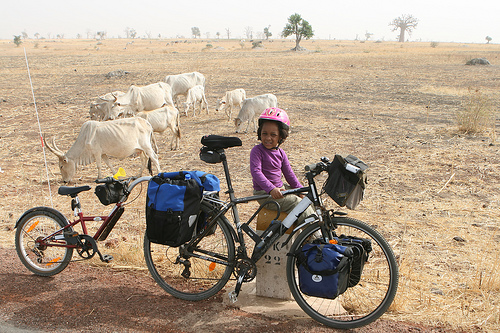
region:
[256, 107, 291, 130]
pink helmet for safety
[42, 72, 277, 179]
grazing white cows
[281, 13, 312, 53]
tree with two trunks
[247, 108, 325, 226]
little girl sitting by the bike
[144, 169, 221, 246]
blue and black storage bags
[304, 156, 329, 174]
bike handle bars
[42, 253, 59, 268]
orange reflectors on the tire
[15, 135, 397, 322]
bicycle with an additional seat and wheel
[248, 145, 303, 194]
purple long sleeve shirt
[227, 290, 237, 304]
metal bike petal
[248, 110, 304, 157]
the head of a girl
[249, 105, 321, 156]
a girl wearing a helmet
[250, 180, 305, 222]
the hand of a girl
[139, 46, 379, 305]
a girl near a bike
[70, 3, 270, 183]
cows in a field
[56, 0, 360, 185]
white cows grazing in a field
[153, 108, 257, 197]
the black seat on a bike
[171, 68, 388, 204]
a girl wearing a purple shirt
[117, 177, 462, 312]
wheels on a bike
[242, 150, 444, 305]
the front wheel on a bike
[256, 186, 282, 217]
the hand of a girl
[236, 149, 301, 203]
the arm of a girl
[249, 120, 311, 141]
the eyes of a girl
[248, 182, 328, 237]
the leg of a girl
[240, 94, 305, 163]
a girl sitting near a bike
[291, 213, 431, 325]
the front wheel of a bike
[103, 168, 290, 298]
the back wheel of a bike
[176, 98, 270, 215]
the seat on a bike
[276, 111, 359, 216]
the handlebars on a bike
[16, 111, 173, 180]
white goat eating food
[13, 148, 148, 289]
red bicycle on dirt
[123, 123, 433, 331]
adult bicycle on dirt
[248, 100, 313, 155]
little girl wearing a pink helmet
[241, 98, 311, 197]
girl wearing a helmet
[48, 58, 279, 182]
white goats standing in back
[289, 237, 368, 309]
blue bag on bike's wheel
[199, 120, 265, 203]
high raised bike seat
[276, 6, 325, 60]
tall tree in back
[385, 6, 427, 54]
tree in the distance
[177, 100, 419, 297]
girl is on bike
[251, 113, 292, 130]
girl has pink helmet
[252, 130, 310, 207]
girl has purple shirt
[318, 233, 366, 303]
blue bag on front of bike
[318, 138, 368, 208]
black bag on handlebars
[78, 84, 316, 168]
white animals behind girl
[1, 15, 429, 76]
few trees on plain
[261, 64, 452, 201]
grass is sparse and brown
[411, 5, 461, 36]
sky is grey and cloudy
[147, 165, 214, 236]
black and blue bag on back of bike